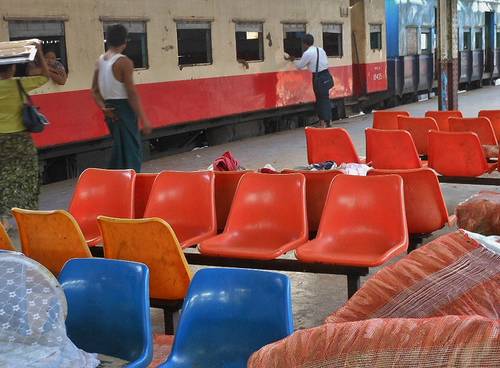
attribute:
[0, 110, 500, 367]
area — for sitting, for waiting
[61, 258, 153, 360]
chair — blue, unoccupied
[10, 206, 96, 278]
chair — orange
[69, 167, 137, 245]
chair — red, orange, unoccupied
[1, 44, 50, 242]
woman — carrying something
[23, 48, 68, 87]
person — leaning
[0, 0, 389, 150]
train car — red, white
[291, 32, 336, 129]
man — talking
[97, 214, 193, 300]
seat — orange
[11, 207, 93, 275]
seat — orange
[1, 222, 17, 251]
seat — orange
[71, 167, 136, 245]
seat — orange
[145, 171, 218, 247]
seat — orange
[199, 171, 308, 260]
seat — orange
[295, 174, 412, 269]
seat — orange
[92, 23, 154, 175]
person — walking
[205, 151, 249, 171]
pile — clothes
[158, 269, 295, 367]
seat — blue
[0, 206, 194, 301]
three seats — orange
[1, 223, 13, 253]
chair — orange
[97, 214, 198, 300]
chair — orange, unoccupied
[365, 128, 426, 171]
chair — unoccupied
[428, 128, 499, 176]
chair — unoccupied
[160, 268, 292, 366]
chair — blue